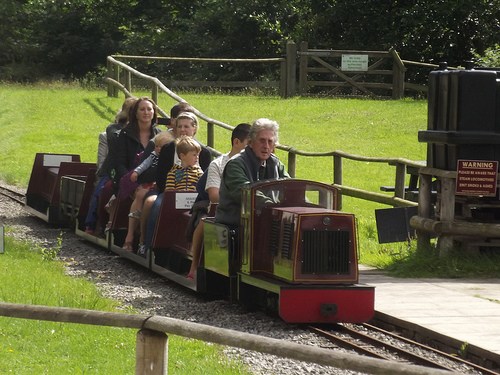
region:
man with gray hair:
[215, 105, 320, 232]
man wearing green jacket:
[205, 105, 295, 241]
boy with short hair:
[200, 99, 267, 228]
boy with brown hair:
[209, 100, 263, 202]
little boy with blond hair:
[162, 132, 203, 211]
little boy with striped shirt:
[152, 131, 223, 202]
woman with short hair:
[134, 96, 213, 188]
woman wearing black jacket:
[146, 115, 223, 200]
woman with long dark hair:
[70, 93, 187, 238]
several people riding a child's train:
[30, 83, 406, 329]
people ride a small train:
[95, 97, 375, 327]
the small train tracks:
[328, 330, 385, 353]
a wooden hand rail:
[4, 297, 281, 372]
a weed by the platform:
[444, 338, 477, 358]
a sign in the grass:
[374, 205, 422, 248]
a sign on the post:
[453, 157, 499, 200]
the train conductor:
[218, 112, 283, 229]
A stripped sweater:
[157, 165, 202, 202]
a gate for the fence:
[292, 45, 397, 97]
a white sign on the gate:
[341, 51, 371, 73]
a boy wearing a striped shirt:
[165, 139, 204, 199]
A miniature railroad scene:
[8, 22, 488, 362]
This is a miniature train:
[16, 95, 388, 333]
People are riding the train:
[86, 93, 218, 253]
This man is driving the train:
[226, 117, 291, 239]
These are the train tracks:
[322, 317, 454, 373]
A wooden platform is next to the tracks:
[380, 264, 497, 361]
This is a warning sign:
[451, 150, 498, 202]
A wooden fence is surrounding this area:
[101, 22, 494, 183]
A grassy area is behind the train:
[4, 85, 88, 180]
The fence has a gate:
[282, 33, 410, 103]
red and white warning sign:
[444, 155, 499, 206]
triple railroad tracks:
[343, 326, 423, 363]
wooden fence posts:
[13, 293, 200, 370]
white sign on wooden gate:
[332, 47, 374, 74]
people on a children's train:
[29, 79, 370, 342]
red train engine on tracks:
[198, 171, 383, 333]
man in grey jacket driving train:
[218, 109, 292, 219]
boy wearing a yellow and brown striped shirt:
[166, 137, 203, 203]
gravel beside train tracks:
[95, 248, 136, 303]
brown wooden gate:
[294, 27, 415, 125]